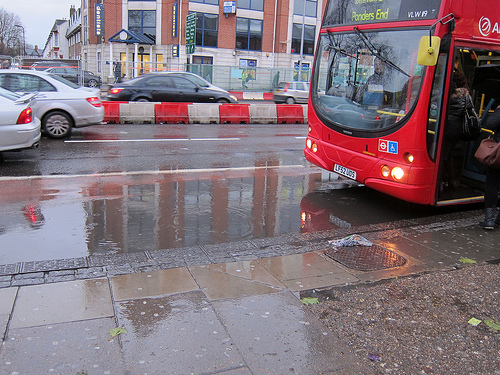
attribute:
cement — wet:
[4, 119, 499, 374]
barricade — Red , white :
[102, 96, 306, 128]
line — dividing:
[3, 158, 305, 179]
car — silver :
[1, 86, 42, 158]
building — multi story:
[79, 0, 321, 101]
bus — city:
[252, 14, 499, 183]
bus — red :
[301, 3, 497, 223]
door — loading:
[431, 36, 498, 214]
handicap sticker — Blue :
[389, 140, 397, 152]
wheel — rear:
[28, 106, 75, 142]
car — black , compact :
[105, 71, 241, 118]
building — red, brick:
[72, 8, 289, 108]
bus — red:
[304, 0, 488, 208]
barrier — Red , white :
[85, 101, 309, 123]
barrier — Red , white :
[228, 89, 273, 101]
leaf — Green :
[98, 305, 147, 342]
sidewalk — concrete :
[3, 208, 499, 373]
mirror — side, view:
[416, 34, 441, 70]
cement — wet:
[0, 162, 430, 265]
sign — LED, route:
[344, 5, 395, 30]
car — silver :
[0, 65, 106, 140]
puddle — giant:
[0, 173, 414, 260]